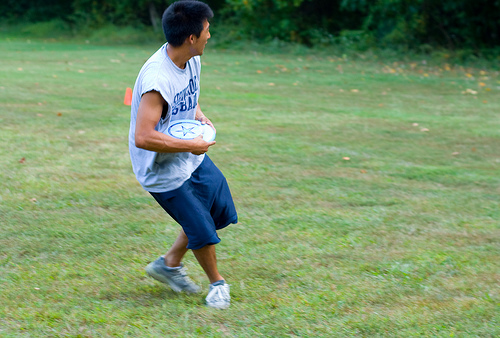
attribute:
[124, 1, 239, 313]
person — holding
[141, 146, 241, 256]
shorts — blue, dark, paired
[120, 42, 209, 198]
shirt — white, vest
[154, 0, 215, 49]
hair — black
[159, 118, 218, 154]
frisbee — round, held, white, activity, blue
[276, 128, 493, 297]
grass — green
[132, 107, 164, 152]
skin — brown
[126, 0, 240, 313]
man — standing, looking, bent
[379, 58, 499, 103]
leaves — brown, dead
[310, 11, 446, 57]
bush — green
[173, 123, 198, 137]
star — on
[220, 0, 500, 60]
trees — green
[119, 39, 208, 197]
vest — grey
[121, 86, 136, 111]
cone — orange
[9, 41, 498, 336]
field — healthy